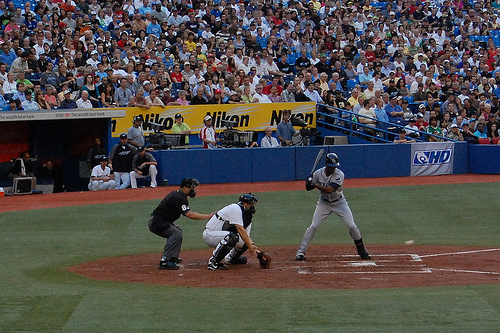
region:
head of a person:
[317, 145, 352, 175]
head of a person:
[242, 179, 274, 214]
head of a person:
[185, 171, 219, 196]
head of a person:
[109, 119, 144, 153]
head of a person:
[93, 143, 123, 171]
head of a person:
[75, 85, 92, 100]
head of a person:
[47, 76, 62, 93]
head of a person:
[15, 61, 33, 82]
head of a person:
[5, 61, 25, 86]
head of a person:
[215, 36, 247, 56]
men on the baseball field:
[86, 136, 383, 330]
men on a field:
[142, 131, 375, 328]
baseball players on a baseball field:
[122, 146, 378, 327]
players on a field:
[98, 113, 413, 315]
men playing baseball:
[122, 114, 417, 314]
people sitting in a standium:
[194, 11, 389, 136]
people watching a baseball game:
[207, 4, 429, 158]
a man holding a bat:
[271, 122, 385, 271]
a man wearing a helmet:
[287, 119, 424, 299]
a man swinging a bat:
[299, 115, 454, 310]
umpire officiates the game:
[146, 177, 220, 269]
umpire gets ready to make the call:
[146, 177, 216, 267]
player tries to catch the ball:
[201, 190, 271, 269]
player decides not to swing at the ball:
[292, 145, 371, 261]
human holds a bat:
[293, 147, 371, 262]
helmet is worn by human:
[322, 150, 339, 170]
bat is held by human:
[305, 145, 325, 183]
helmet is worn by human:
[236, 188, 258, 213]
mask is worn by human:
[180, 175, 200, 197]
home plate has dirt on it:
[345, 257, 378, 270]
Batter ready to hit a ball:
[292, 145, 377, 262]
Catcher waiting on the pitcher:
[200, 190, 273, 295]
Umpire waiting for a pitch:
[142, 172, 215, 270]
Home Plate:
[345, 258, 376, 268]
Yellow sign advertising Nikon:
[108, 102, 313, 130]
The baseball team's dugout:
[0, 112, 110, 195]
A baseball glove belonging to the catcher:
[253, 247, 273, 268]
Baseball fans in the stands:
[0, 0, 499, 145]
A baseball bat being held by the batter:
[306, 145, 326, 185]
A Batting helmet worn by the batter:
[323, 151, 341, 171]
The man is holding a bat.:
[281, 133, 324, 189]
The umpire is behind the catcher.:
[146, 174, 219, 289]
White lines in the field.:
[390, 240, 471, 273]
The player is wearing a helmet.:
[316, 151, 341, 167]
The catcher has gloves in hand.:
[257, 242, 272, 274]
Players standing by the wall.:
[73, 130, 169, 189]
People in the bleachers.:
[118, 17, 479, 112]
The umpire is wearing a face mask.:
[182, 169, 204, 194]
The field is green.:
[362, 182, 466, 254]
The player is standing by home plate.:
[346, 247, 418, 289]